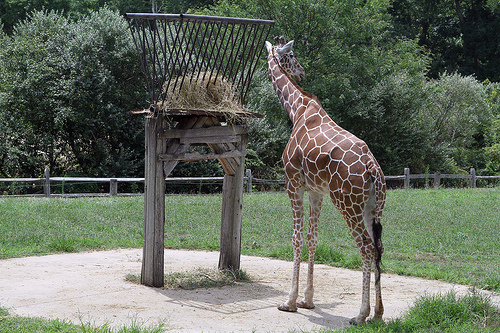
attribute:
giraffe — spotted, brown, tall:
[266, 35, 385, 323]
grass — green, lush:
[2, 188, 499, 332]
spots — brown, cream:
[292, 133, 331, 168]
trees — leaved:
[0, 0, 497, 175]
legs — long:
[276, 181, 384, 323]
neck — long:
[267, 46, 323, 127]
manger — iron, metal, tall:
[127, 10, 273, 111]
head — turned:
[266, 35, 308, 81]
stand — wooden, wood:
[142, 117, 247, 285]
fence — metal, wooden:
[1, 166, 498, 194]